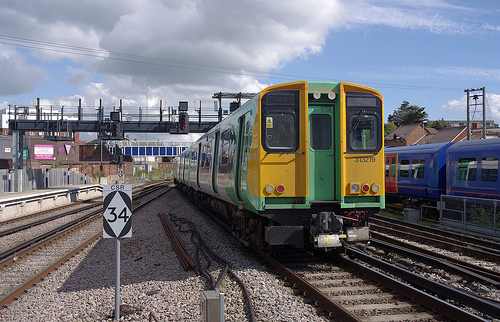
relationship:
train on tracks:
[177, 81, 388, 250] [289, 245, 494, 320]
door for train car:
[306, 100, 342, 201] [175, 81, 386, 246]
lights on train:
[264, 181, 382, 196] [177, 81, 388, 250]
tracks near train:
[233, 210, 498, 285] [174, 73, 394, 256]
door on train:
[306, 100, 338, 201] [173, 85, 386, 271]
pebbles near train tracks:
[3, 183, 335, 320] [282, 249, 479, 297]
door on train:
[306, 100, 342, 201] [177, 81, 388, 250]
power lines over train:
[2, 32, 497, 97] [174, 73, 394, 256]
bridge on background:
[11, 105, 247, 137] [27, 43, 177, 187]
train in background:
[386, 137, 498, 209] [385, 98, 494, 135]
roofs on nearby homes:
[384, 122, 499, 143] [376, 114, 497, 155]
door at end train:
[306, 100, 342, 201] [160, 87, 387, 245]